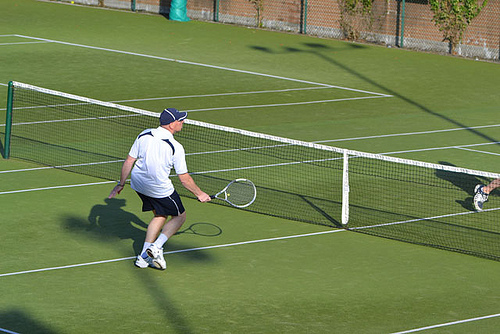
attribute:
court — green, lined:
[0, 0, 498, 333]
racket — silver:
[199, 173, 261, 220]